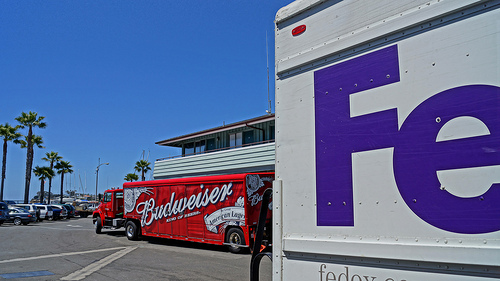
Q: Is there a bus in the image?
A: No, there are no buses.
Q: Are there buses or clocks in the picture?
A: No, there are no buses or clocks.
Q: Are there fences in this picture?
A: No, there are no fences.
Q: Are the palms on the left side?
A: Yes, the palms are on the left of the image.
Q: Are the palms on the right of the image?
A: No, the palms are on the left of the image.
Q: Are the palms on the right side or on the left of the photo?
A: The palms are on the left of the image.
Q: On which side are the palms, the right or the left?
A: The palms are on the left of the image.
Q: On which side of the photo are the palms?
A: The palms are on the left of the image.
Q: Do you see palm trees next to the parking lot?
A: Yes, there are palm trees next to the parking lot.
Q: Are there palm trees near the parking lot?
A: Yes, there are palm trees near the parking lot.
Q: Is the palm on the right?
A: No, the palm is on the left of the image.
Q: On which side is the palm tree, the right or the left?
A: The palm tree is on the left of the image.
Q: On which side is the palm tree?
A: The palm tree is on the left of the image.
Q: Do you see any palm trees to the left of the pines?
A: Yes, there is a palm tree to the left of the pines.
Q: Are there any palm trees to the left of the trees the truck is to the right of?
A: Yes, there is a palm tree to the left of the pines.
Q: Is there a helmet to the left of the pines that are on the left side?
A: No, there is a palm tree to the left of the pines.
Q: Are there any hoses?
A: No, there are no hoses.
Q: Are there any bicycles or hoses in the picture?
A: No, there are no hoses or bicycles.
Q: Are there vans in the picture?
A: No, there are no vans.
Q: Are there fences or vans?
A: No, there are no vans or fences.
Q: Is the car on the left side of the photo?
A: Yes, the car is on the left of the image.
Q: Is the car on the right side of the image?
A: No, the car is on the left of the image.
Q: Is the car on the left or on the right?
A: The car is on the left of the image.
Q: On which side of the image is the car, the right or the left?
A: The car is on the left of the image.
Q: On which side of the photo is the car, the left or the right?
A: The car is on the left of the image.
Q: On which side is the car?
A: The car is on the left of the image.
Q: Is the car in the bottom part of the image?
A: Yes, the car is in the bottom of the image.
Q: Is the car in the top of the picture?
A: No, the car is in the bottom of the image.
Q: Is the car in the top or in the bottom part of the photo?
A: The car is in the bottom of the image.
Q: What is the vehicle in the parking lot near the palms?
A: The vehicle is a car.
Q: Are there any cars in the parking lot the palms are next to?
A: Yes, there is a car in the parking lot.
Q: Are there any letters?
A: Yes, there are letters.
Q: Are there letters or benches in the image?
A: Yes, there are letters.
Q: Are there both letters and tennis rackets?
A: No, there are letters but no rackets.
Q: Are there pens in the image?
A: No, there are no pens.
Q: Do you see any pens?
A: No, there are no pens.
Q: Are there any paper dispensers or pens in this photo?
A: No, there are no pens or paper dispensers.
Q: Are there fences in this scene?
A: No, there are no fences.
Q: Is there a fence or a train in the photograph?
A: No, there are no fences or trains.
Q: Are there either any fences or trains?
A: No, there are no fences or trains.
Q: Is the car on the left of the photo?
A: Yes, the car is on the left of the image.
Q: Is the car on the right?
A: No, the car is on the left of the image.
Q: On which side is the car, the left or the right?
A: The car is on the left of the image.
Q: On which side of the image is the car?
A: The car is on the left of the image.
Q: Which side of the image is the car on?
A: The car is on the left of the image.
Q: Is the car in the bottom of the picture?
A: Yes, the car is in the bottom of the image.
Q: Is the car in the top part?
A: No, the car is in the bottom of the image.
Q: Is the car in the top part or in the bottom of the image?
A: The car is in the bottom of the image.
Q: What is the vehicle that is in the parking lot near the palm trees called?
A: The vehicle is a car.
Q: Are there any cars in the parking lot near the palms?
A: Yes, there is a car in the parking lot.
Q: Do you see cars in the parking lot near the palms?
A: Yes, there is a car in the parking lot.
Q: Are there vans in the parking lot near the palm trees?
A: No, there is a car in the parking lot.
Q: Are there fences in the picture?
A: No, there are no fences.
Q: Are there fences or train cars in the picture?
A: No, there are no fences or train cars.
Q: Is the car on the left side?
A: Yes, the car is on the left of the image.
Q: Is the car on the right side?
A: No, the car is on the left of the image.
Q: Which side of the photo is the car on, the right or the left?
A: The car is on the left of the image.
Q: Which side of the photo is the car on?
A: The car is on the left of the image.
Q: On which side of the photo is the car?
A: The car is on the left of the image.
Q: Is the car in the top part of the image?
A: No, the car is in the bottom of the image.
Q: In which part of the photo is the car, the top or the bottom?
A: The car is in the bottom of the image.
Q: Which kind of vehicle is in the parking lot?
A: The vehicle is a car.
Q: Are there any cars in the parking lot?
A: Yes, there is a car in the parking lot.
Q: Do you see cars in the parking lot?
A: Yes, there is a car in the parking lot.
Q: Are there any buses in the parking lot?
A: No, there is a car in the parking lot.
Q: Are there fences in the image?
A: No, there are no fences.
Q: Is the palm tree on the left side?
A: Yes, the palm tree is on the left of the image.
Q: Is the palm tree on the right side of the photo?
A: No, the palm tree is on the left of the image.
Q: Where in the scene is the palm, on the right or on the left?
A: The palm is on the left of the image.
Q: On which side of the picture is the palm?
A: The palm is on the left of the image.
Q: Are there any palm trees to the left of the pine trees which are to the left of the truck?
A: Yes, there is a palm tree to the left of the pines.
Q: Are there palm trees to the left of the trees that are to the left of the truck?
A: Yes, there is a palm tree to the left of the pines.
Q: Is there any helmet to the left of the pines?
A: No, there is a palm tree to the left of the pines.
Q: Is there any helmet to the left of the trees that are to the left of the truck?
A: No, there is a palm tree to the left of the pines.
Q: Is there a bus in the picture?
A: No, there are no buses.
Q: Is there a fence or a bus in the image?
A: No, there are no buses or fences.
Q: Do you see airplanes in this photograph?
A: No, there are no airplanes.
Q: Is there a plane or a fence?
A: No, there are no airplanes or fences.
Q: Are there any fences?
A: No, there are no fences.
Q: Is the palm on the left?
A: Yes, the palm is on the left of the image.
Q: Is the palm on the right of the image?
A: No, the palm is on the left of the image.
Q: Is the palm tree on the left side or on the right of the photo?
A: The palm tree is on the left of the image.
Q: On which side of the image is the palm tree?
A: The palm tree is on the left of the image.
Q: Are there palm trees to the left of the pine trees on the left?
A: Yes, there is a palm tree to the left of the pine trees.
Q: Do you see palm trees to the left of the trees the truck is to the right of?
A: Yes, there is a palm tree to the left of the pine trees.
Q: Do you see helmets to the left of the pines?
A: No, there is a palm tree to the left of the pines.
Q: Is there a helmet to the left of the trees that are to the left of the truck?
A: No, there is a palm tree to the left of the pines.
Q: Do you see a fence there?
A: No, there are no fences.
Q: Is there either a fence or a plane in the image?
A: No, there are no fences or airplanes.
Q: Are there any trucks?
A: Yes, there is a truck.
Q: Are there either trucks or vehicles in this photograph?
A: Yes, there is a truck.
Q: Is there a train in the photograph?
A: No, there are no trains.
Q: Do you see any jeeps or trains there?
A: No, there are no trains or jeeps.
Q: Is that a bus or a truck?
A: That is a truck.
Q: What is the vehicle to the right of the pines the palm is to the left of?
A: The vehicle is a truck.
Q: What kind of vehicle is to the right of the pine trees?
A: The vehicle is a truck.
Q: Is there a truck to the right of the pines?
A: Yes, there is a truck to the right of the pines.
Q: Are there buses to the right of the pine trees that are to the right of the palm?
A: No, there is a truck to the right of the pine trees.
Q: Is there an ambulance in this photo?
A: No, there are no ambulances.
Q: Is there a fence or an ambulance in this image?
A: No, there are no ambulances or fences.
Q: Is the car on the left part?
A: Yes, the car is on the left of the image.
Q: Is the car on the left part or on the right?
A: The car is on the left of the image.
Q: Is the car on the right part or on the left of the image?
A: The car is on the left of the image.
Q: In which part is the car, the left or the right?
A: The car is on the left of the image.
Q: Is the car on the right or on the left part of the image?
A: The car is on the left of the image.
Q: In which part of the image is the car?
A: The car is on the left of the image.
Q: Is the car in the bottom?
A: Yes, the car is in the bottom of the image.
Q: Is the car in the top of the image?
A: No, the car is in the bottom of the image.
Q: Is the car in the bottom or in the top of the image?
A: The car is in the bottom of the image.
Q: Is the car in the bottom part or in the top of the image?
A: The car is in the bottom of the image.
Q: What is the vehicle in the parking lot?
A: The vehicle is a car.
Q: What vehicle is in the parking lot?
A: The vehicle is a car.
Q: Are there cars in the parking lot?
A: Yes, there is a car in the parking lot.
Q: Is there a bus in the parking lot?
A: No, there is a car in the parking lot.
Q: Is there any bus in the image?
A: No, there are no buses.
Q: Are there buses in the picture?
A: No, there are no buses.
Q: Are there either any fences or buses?
A: No, there are no buses or fences.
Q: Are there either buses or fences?
A: No, there are no buses or fences.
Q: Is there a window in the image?
A: Yes, there is a window.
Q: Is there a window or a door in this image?
A: Yes, there is a window.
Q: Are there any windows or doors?
A: Yes, there is a window.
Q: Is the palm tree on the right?
A: No, the palm tree is on the left of the image.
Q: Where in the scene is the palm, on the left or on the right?
A: The palm is on the left of the image.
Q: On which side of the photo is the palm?
A: The palm is on the left of the image.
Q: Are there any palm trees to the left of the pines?
A: Yes, there is a palm tree to the left of the pines.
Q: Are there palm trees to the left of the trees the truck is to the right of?
A: Yes, there is a palm tree to the left of the pines.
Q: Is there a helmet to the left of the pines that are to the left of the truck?
A: No, there is a palm tree to the left of the pines.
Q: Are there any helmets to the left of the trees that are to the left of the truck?
A: No, there is a palm tree to the left of the pines.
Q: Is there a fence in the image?
A: No, there are no fences.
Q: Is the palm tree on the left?
A: Yes, the palm tree is on the left of the image.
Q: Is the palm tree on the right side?
A: No, the palm tree is on the left of the image.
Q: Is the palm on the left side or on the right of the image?
A: The palm is on the left of the image.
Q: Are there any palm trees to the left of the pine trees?
A: Yes, there is a palm tree to the left of the pine trees.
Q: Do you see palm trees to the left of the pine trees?
A: Yes, there is a palm tree to the left of the pine trees.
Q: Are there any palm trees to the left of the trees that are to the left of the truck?
A: Yes, there is a palm tree to the left of the pine trees.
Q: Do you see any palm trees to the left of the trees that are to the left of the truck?
A: Yes, there is a palm tree to the left of the pine trees.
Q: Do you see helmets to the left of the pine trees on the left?
A: No, there is a palm tree to the left of the pines.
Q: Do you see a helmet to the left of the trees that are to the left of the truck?
A: No, there is a palm tree to the left of the pines.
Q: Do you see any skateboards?
A: No, there are no skateboards.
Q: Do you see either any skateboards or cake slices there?
A: No, there are no skateboards or cake slices.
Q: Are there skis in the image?
A: No, there are no skis.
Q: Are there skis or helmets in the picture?
A: No, there are no skis or helmets.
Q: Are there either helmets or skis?
A: No, there are no skis or helmets.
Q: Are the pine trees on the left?
A: Yes, the pine trees are on the left of the image.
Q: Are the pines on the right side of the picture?
A: No, the pines are on the left of the image.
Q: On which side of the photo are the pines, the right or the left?
A: The pines are on the left of the image.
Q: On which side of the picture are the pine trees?
A: The pine trees are on the left of the image.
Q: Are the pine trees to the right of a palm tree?
A: Yes, the pine trees are to the right of a palm tree.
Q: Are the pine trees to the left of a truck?
A: Yes, the pine trees are to the left of a truck.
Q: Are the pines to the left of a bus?
A: No, the pines are to the left of a truck.